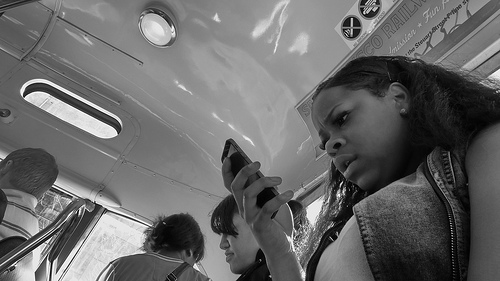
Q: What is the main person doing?
A: Looking at a cell phone.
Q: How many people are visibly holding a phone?
A: One.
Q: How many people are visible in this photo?
A: Four.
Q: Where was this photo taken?
A: On a bus.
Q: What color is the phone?
A: Black.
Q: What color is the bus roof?
A: White.